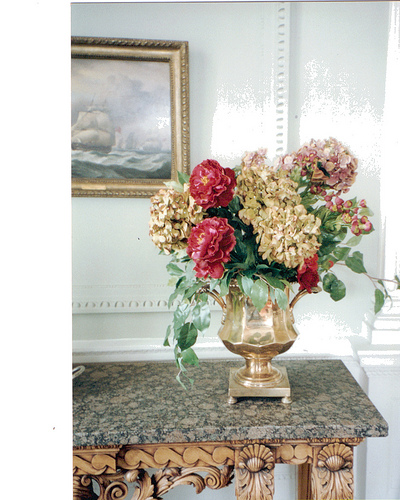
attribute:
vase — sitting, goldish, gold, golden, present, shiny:
[186, 275, 323, 405]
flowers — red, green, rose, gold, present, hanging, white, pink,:
[148, 135, 399, 393]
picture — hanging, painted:
[72, 57, 174, 181]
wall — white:
[72, 2, 399, 361]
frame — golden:
[72, 35, 192, 199]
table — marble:
[70, 358, 389, 499]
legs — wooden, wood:
[237, 437, 355, 499]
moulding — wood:
[72, 1, 292, 316]